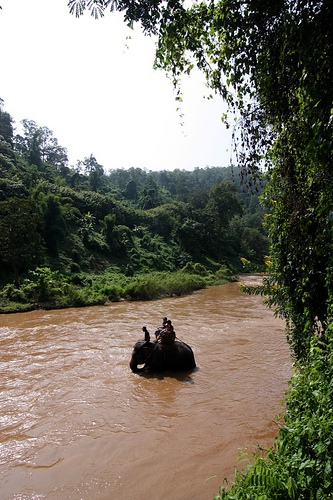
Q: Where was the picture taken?
A: It was taken at the river.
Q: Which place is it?
A: It is a river.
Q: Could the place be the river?
A: Yes, it is the river.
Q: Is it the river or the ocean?
A: It is the river.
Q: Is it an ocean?
A: No, it is a river.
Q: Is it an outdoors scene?
A: Yes, it is outdoors.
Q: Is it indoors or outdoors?
A: It is outdoors.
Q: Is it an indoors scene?
A: No, it is outdoors.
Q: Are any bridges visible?
A: No, there are no bridges.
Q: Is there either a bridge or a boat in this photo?
A: No, there are no bridges or boats.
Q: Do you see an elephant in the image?
A: Yes, there is an elephant.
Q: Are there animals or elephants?
A: Yes, there is an elephant.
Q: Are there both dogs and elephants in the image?
A: No, there is an elephant but no dogs.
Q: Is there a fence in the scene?
A: No, there are no fences.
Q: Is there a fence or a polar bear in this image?
A: No, there are no fences or polar bears.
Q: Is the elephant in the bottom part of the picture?
A: Yes, the elephant is in the bottom of the image.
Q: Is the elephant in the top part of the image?
A: No, the elephant is in the bottom of the image.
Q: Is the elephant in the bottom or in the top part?
A: The elephant is in the bottom of the image.